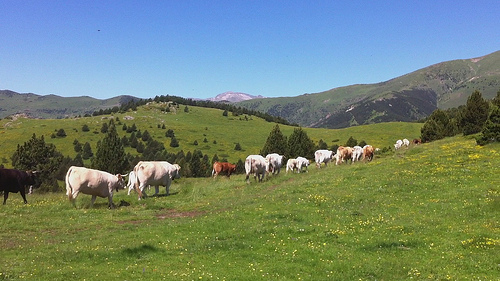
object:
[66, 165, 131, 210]
cows